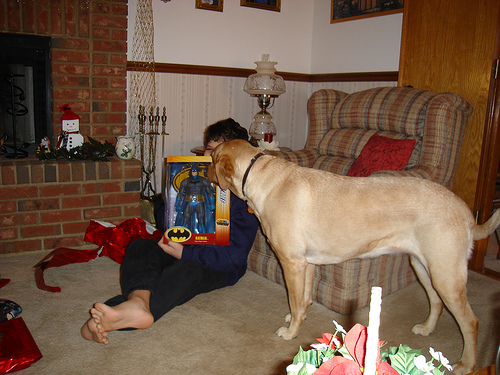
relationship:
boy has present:
[75, 116, 260, 346] [158, 149, 233, 250]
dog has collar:
[202, 136, 497, 374] [240, 149, 269, 200]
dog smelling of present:
[202, 136, 497, 374] [158, 149, 233, 250]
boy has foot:
[75, 116, 260, 346] [88, 298, 157, 332]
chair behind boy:
[247, 82, 477, 317] [75, 116, 260, 346]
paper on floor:
[27, 212, 169, 300] [0, 250, 494, 374]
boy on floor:
[75, 116, 260, 346] [0, 250, 494, 374]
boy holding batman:
[75, 116, 260, 346] [161, 152, 235, 248]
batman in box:
[161, 152, 235, 248] [162, 152, 232, 248]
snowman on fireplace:
[53, 101, 88, 158] [2, 0, 143, 260]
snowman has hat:
[53, 101, 88, 158] [58, 101, 82, 122]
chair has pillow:
[247, 82, 477, 317] [341, 129, 421, 180]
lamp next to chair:
[243, 50, 286, 154] [247, 82, 477, 317]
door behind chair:
[399, 0, 499, 272] [247, 82, 477, 317]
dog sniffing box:
[202, 136, 497, 374] [162, 152, 232, 248]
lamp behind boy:
[243, 50, 286, 154] [75, 116, 260, 346]